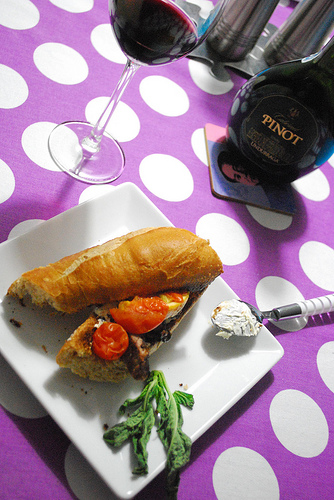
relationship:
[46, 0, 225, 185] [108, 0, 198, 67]
wine glass with wine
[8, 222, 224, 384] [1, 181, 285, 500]
sandwich on top of plate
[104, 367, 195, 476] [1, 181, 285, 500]
garnish on top of plate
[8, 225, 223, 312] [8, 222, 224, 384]
loaf on top of sandwich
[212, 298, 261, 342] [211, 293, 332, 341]
condiment on spoon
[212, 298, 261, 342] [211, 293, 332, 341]
condiment held by spoon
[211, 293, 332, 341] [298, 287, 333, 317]
spoon has handle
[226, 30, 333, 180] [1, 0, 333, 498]
wine bottle on top of table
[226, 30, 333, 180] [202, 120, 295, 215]
wine bottle on top of coaster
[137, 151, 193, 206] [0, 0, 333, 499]
dot on top of tablecloth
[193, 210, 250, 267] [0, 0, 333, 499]
dot on top of tablecloth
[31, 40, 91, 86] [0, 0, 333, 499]
dot on top of tablecloth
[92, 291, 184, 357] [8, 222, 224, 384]
tomato inside of sandwich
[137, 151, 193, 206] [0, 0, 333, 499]
dot part of tablecloth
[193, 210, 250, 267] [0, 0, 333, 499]
dot part of tablecloth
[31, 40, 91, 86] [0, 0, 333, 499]
dot part of tablecloth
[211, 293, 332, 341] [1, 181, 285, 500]
spoon leaning on plate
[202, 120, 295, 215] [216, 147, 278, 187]
coaster with picture of chinese leader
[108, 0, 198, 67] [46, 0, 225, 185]
wine inside of wine glass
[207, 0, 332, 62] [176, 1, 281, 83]
containers on top of tray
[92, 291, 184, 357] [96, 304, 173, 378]
tomato on top of meats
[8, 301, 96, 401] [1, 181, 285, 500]
crumbs on top of plate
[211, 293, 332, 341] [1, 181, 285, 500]
spoon leaning against plate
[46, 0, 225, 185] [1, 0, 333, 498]
wine glass on top of table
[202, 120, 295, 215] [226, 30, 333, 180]
coaster below wine bottle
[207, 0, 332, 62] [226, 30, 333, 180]
containers behind wine bottle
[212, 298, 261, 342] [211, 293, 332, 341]
condiment on top of spoon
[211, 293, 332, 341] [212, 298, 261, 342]
spoon holding condiment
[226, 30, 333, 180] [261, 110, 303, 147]
wine bottle says pinot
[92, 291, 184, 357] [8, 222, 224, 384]
tomato inside sandwich